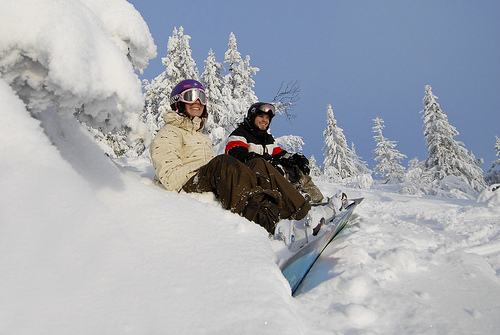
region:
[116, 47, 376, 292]
couple sit on the snow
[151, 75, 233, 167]
woman wear goggles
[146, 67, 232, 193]
woman wears a white coat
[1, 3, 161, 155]
tree covered with snow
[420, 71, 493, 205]
tree covered with snow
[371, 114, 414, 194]
tree covered with snow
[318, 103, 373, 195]
tree covered with snow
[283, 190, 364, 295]
snowboard on the snow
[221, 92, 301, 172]
man has goggles on front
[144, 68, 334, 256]
woman wears black pants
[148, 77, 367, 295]
Two people enjoy snowboarding.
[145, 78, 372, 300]
Two people rest on a snow bank.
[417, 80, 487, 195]
The snow covered tree.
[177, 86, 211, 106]
The person wears goggles.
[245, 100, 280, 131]
The man smiles big.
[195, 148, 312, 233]
The snow pants are brown.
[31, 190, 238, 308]
The undisturbed snow.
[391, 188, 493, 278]
The snow has tracks.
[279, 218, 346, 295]
The snow board.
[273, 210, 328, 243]
They wear snow boots.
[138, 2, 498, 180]
blue of daytime sky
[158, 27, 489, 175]
pine trees covered in snow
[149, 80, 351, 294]
two people sitting on snow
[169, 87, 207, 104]
goggles on woman's face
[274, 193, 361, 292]
snowboards attached to boots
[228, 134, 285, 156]
red and white stripe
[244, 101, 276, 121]
goggles on front of helmet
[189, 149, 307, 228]
brown snow pants on legs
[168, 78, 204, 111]
purple helmet on head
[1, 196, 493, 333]
snow on ground surface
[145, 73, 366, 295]
two snowboarders sitting in the snow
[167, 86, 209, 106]
pink goggles on the woman's face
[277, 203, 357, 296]
a snowboard under the woman's feet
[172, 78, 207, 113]
a purple helmet on the woman's head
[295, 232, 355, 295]
the shadow of the snowboard in the snow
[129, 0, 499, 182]
a clear blue sky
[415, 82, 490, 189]
a tree covered in snow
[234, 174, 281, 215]
bits of snow on the woman's pants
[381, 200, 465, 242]
tracks in the snow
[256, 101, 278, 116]
reflective goggles on the man's head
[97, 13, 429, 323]
two people are sitting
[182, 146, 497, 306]
the girl has brown pants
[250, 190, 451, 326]
the woman's feet are attached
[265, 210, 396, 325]
the snowboard is on the woman's feet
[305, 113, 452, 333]
snow covered trees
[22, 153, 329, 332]
snow covered hill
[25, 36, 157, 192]
clumps of snow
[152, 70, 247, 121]
the woman is wearing goggles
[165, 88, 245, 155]
the woman is wearing a helmet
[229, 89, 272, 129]
the man is wearing a helmet